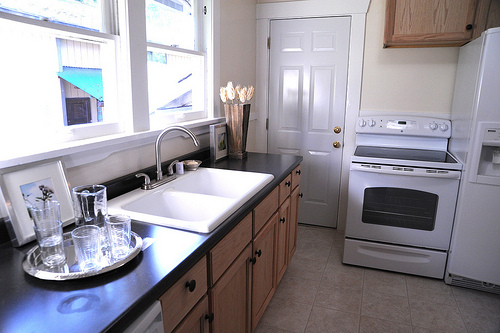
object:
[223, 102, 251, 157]
vase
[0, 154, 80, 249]
pitcher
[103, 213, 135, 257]
glass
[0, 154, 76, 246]
photot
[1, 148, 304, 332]
counter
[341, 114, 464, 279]
oven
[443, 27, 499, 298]
fridge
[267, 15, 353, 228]
door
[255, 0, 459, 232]
wall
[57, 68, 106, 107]
awning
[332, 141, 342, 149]
knob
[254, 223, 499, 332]
floor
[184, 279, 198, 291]
pull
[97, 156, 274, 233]
sink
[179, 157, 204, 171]
soap dish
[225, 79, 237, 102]
flower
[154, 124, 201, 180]
faucet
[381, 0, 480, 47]
cabinet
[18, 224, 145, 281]
tray